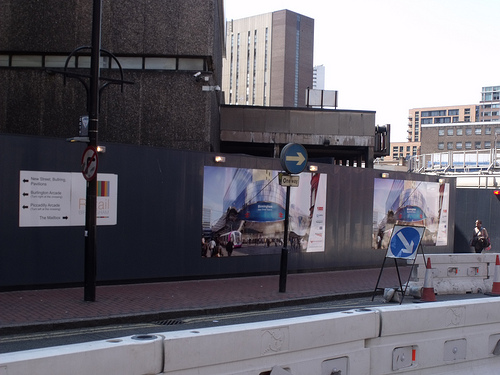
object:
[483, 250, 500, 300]
cone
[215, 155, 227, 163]
light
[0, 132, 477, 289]
grey wall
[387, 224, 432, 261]
street sign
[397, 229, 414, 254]
arrow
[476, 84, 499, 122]
buildings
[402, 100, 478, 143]
buildings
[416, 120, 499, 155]
buildings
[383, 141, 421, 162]
buildings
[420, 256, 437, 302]
cone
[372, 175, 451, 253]
poster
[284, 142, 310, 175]
sign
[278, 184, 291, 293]
pole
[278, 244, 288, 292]
bottom part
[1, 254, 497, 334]
sidewalk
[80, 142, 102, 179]
sign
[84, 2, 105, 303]
post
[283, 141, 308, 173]
blue sign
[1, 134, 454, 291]
barrier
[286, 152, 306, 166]
arrow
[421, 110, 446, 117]
windows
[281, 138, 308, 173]
sign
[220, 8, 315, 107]
building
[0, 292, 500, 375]
barricade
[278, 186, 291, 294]
post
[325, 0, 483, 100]
sky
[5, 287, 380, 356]
street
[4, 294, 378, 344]
line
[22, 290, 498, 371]
construction barrier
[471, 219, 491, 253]
pedestrian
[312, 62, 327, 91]
building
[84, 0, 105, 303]
bottom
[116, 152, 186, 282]
wall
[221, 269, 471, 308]
ground